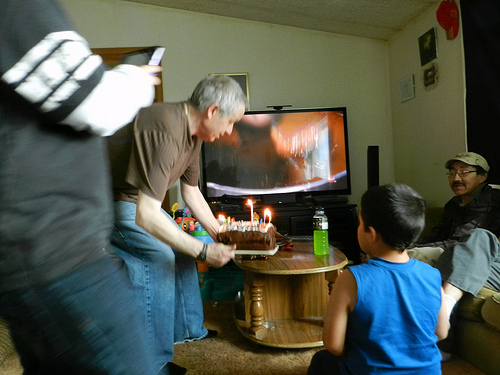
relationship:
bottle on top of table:
[310, 205, 332, 257] [230, 240, 352, 351]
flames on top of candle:
[246, 197, 254, 207] [247, 206, 256, 226]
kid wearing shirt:
[307, 181, 449, 374] [341, 260, 442, 374]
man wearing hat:
[417, 151, 500, 316] [444, 151, 492, 173]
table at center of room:
[230, 240, 352, 351] [1, 0, 500, 372]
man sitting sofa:
[417, 151, 500, 316] [415, 206, 499, 374]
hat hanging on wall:
[434, 0, 461, 42] [67, 0, 470, 205]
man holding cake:
[105, 73, 248, 373] [214, 221, 276, 250]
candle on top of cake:
[247, 206, 256, 226] [214, 221, 276, 250]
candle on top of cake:
[260, 208, 268, 226] [214, 221, 276, 250]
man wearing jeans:
[105, 73, 248, 373] [109, 199, 208, 367]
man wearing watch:
[105, 73, 248, 373] [195, 242, 211, 263]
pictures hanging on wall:
[397, 25, 442, 104] [67, 0, 470, 205]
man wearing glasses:
[417, 151, 500, 316] [446, 169, 478, 176]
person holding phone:
[0, 2, 167, 374] [119, 45, 164, 68]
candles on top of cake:
[216, 198, 274, 227] [214, 221, 276, 250]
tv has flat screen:
[196, 104, 355, 207] [200, 106, 352, 198]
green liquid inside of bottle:
[312, 231, 331, 255] [310, 205, 332, 257]